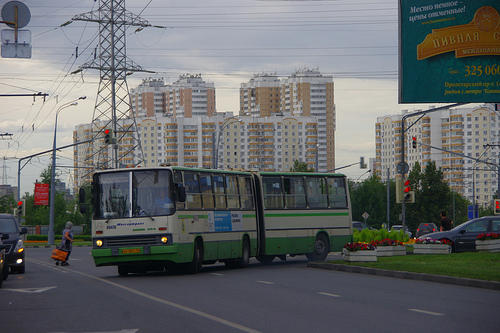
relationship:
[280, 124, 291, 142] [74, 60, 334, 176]
window on side of building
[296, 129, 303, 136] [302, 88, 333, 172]
window on side of building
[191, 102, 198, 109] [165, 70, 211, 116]
window on side of building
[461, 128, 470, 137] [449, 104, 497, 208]
window on side of building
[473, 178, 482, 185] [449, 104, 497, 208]
window on side of building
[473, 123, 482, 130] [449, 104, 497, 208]
window on side of building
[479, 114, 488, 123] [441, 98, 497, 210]
window on side of building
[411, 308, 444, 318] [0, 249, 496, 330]
line on pavement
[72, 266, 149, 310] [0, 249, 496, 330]
white line on pavement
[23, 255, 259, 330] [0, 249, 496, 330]
line on pavement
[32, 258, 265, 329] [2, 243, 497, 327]
line on pavement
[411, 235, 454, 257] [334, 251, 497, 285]
white flower pot on grass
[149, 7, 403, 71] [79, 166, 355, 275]
power lines behind "white and green bus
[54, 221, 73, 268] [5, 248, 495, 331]
human crosses street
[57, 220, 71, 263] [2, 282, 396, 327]
person walking in road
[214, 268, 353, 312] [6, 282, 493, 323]
white dashed lines on road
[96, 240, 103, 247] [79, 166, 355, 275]
bus headlights on "white and green bus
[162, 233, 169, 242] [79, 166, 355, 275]
headlight on "white and green bus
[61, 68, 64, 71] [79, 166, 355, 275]
power lines over "white and green bus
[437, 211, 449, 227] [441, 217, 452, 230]
man wearing black shirt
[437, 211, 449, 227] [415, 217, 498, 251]
man standing by car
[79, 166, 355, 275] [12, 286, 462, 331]
"white and green bus on street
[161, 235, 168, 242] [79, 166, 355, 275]
light on "white and green bus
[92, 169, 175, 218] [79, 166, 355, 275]
he windshield on "white and green bus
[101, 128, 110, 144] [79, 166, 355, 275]
traffic light over "white and green bus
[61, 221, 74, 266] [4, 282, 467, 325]
person crossing street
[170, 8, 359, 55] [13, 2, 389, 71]
clouds in sky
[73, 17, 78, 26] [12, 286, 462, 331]
power lines above street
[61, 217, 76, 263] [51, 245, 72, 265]
human towing something